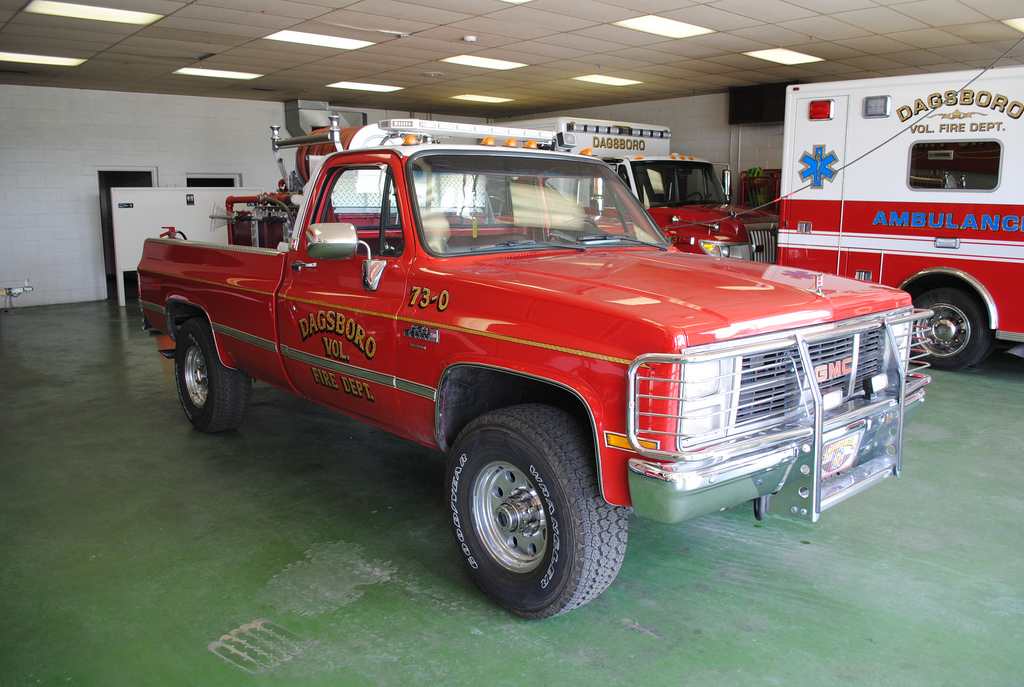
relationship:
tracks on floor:
[209, 617, 311, 678] [5, 299, 1022, 681]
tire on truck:
[444, 400, 624, 621] [135, 142, 934, 622]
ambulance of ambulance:
[777, 64, 1024, 368] [773, 60, 1022, 365]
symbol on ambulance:
[799, 147, 836, 190] [773, 60, 1022, 365]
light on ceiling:
[442, 52, 524, 74] [2, 2, 1022, 117]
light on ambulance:
[803, 98, 835, 119] [773, 60, 1022, 365]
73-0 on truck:
[407, 285, 450, 313] [135, 142, 934, 622]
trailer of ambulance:
[487, 116, 668, 211] [498, 119, 775, 270]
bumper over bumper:
[627, 305, 934, 524] [586, 280, 914, 522]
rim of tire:
[472, 459, 546, 576] [444, 400, 624, 621]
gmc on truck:
[814, 360, 854, 386] [135, 142, 934, 622]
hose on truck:
[277, 116, 400, 186] [135, 142, 934, 622]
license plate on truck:
[817, 435, 867, 479] [135, 142, 934, 622]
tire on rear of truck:
[171, 314, 247, 435] [135, 142, 934, 622]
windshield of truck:
[407, 148, 670, 259] [135, 142, 934, 622]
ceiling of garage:
[2, 2, 1022, 117] [6, 1, 1022, 686]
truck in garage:
[135, 142, 934, 622] [6, 1, 1022, 686]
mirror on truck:
[304, 222, 382, 292] [135, 142, 934, 622]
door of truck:
[276, 154, 415, 442] [135, 142, 934, 622]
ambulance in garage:
[773, 60, 1022, 365] [6, 1, 1022, 686]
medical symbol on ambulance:
[799, 147, 836, 190] [773, 60, 1022, 365]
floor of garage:
[5, 299, 1022, 681] [6, 1, 1022, 686]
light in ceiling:
[442, 52, 524, 74] [2, 2, 1022, 117]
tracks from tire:
[209, 617, 311, 678] [444, 400, 624, 621]